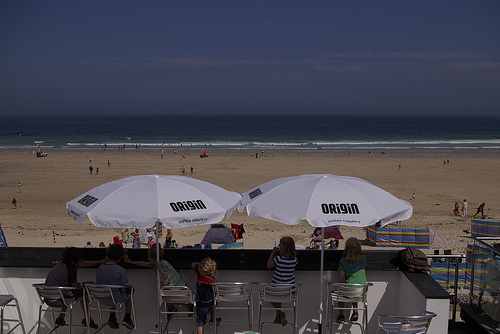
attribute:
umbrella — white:
[276, 176, 377, 231]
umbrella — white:
[233, 167, 415, 231]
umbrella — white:
[62, 169, 243, 234]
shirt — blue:
[95, 263, 125, 300]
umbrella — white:
[55, 166, 242, 237]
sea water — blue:
[0, 115, 499, 152]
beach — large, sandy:
[1, 142, 498, 253]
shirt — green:
[350, 262, 366, 282]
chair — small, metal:
[210, 276, 262, 332]